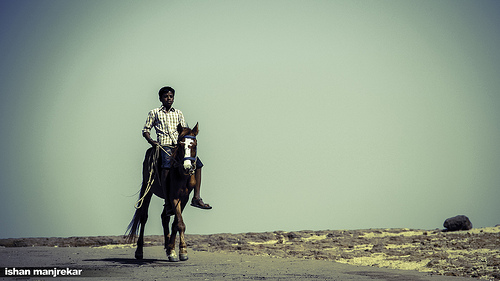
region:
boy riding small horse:
[130, 88, 212, 262]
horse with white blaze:
[119, 117, 209, 270]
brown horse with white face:
[120, 118, 205, 263]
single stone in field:
[429, 208, 492, 237]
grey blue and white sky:
[1, 1, 495, 227]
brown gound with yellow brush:
[204, 222, 493, 277]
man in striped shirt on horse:
[125, 78, 212, 258]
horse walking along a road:
[127, 117, 204, 265]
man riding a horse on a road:
[119, 81, 216, 269]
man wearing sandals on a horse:
[129, 80, 214, 279]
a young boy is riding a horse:
[130, 85, 215, 262]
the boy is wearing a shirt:
[139, 108, 185, 144]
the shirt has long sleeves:
[145, 102, 187, 150]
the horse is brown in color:
[132, 143, 204, 259]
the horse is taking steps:
[137, 128, 213, 261]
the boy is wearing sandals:
[190, 193, 214, 210]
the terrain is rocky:
[5, 228, 494, 278]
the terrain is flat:
[5, 228, 499, 279]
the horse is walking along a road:
[0, 231, 422, 279]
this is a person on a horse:
[87, 61, 255, 262]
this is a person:
[120, 68, 198, 183]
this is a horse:
[112, 112, 224, 274]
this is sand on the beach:
[290, 225, 377, 276]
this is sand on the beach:
[394, 226, 418, 260]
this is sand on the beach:
[435, 225, 470, 273]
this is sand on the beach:
[365, 219, 459, 271]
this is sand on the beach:
[232, 225, 343, 243]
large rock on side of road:
[442, 215, 472, 228]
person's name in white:
[1, 265, 84, 278]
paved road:
[3, 243, 477, 279]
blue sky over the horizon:
[0, 0, 499, 237]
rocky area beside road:
[2, 229, 499, 277]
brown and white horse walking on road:
[123, 125, 190, 262]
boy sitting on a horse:
[143, 86, 213, 209]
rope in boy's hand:
[134, 143, 171, 208]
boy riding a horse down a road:
[126, 86, 215, 263]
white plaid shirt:
[142, 105, 186, 145]